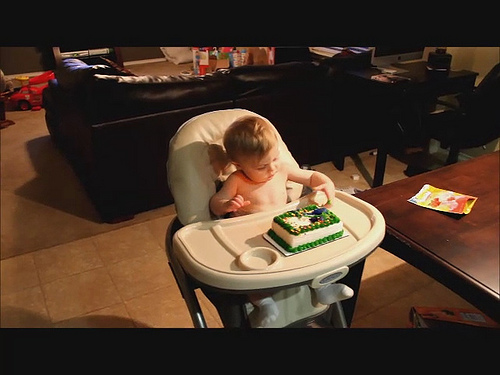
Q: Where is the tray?
A: On high chair.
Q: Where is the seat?
A: High chair.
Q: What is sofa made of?
A: Leather.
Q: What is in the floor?
A: Rug.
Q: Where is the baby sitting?
A: In a high chair.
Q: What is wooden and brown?
A: The table.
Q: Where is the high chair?
A: Next to the table.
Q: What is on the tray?
A: A cake.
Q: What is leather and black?
A: Couch.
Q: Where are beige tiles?
A: On the floor.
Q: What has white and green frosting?
A: The cake.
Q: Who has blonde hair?
A: The baby.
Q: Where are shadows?
A: On the floor.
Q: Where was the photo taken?
A: In a house.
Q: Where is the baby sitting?
A: High chair.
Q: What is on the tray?
A: Cake.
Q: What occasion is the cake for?
A: Birthday.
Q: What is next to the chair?
A: Dining table.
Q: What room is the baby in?
A: Dining room.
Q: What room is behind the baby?
A: Living room.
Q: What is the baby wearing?
A: Socks.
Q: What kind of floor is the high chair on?
A: Beige tile.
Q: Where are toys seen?
A: Carpet next to couch.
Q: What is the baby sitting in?
A: A high chair.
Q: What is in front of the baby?
A: Birthday cake.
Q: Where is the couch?
A: Behind the baby.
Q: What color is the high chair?
A: White.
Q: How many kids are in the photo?
A: One.